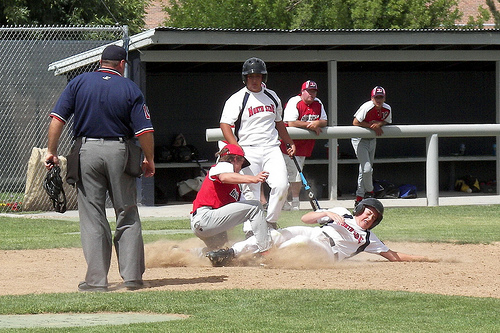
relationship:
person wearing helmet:
[246, 110, 285, 219] [242, 57, 268, 85]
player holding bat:
[218, 51, 328, 253] [282, 141, 333, 234]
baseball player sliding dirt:
[214, 193, 398, 265] [1, 235, 498, 331]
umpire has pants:
[42, 42, 156, 291] [65, 132, 155, 283]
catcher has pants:
[190, 142, 274, 262] [191, 200, 272, 250]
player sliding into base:
[210, 196, 435, 265] [266, 254, 316, 267]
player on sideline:
[345, 82, 393, 208] [204, 157, 496, 250]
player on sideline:
[281, 75, 332, 211] [204, 157, 496, 250]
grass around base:
[1, 203, 498, 331] [203, 277, 329, 331]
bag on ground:
[390, 183, 418, 200] [380, 181, 470, 238]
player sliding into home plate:
[232, 190, 440, 265] [164, 247, 217, 269]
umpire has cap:
[31, 35, 169, 295] [91, 41, 135, 68]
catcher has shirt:
[187, 142, 290, 270] [185, 155, 247, 212]